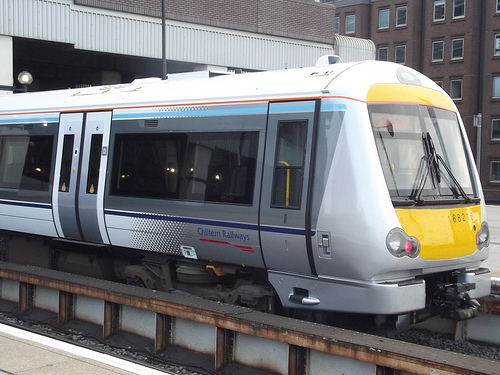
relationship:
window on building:
[429, 37, 448, 66] [334, 7, 499, 200]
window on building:
[429, 37, 444, 61] [334, 7, 499, 200]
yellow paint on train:
[368, 82, 483, 259] [0, 50, 498, 322]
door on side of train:
[74, 110, 113, 248] [0, 50, 498, 322]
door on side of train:
[50, 110, 83, 243] [0, 50, 498, 322]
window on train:
[113, 132, 270, 207] [0, 12, 480, 342]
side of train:
[0, 97, 353, 319] [0, 50, 498, 322]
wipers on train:
[409, 131, 472, 200] [0, 50, 498, 322]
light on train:
[381, 222, 498, 257] [0, 50, 498, 322]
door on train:
[74, 110, 115, 248] [0, 50, 498, 322]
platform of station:
[1, 313, 180, 374] [0, 0, 497, 372]